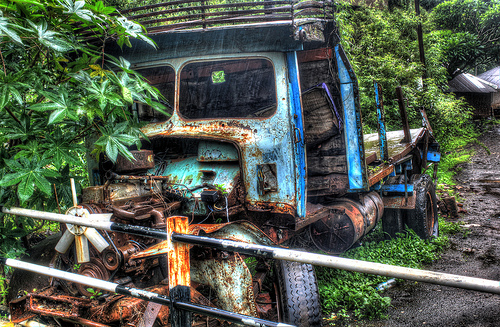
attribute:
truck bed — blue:
[332, 122, 439, 192]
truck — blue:
[1, 0, 443, 325]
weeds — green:
[327, 223, 433, 310]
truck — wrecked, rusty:
[77, 141, 314, 315]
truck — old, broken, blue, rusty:
[81, 15, 441, 325]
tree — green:
[14, 20, 139, 195]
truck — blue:
[116, 20, 394, 250]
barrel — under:
[307, 191, 385, 253]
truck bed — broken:
[359, 125, 433, 178]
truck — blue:
[57, 26, 440, 318]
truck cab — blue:
[79, 28, 372, 223]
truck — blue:
[68, 11, 430, 285]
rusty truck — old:
[73, 5, 440, 320]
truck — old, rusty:
[64, 17, 416, 302]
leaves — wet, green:
[12, 22, 144, 143]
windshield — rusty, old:
[124, 61, 182, 124]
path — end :
[409, 133, 485, 307]